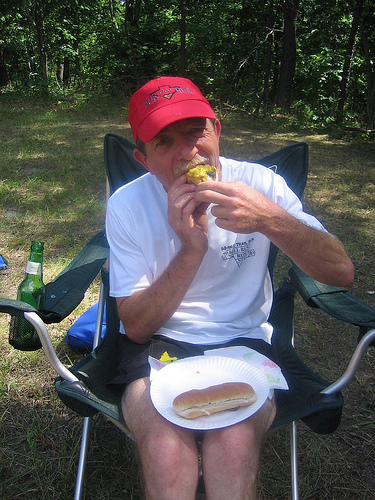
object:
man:
[103, 75, 353, 500]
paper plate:
[148, 355, 270, 432]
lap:
[137, 427, 201, 494]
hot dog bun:
[173, 381, 258, 420]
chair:
[3, 135, 375, 500]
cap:
[128, 74, 217, 147]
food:
[186, 164, 218, 188]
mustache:
[173, 157, 208, 176]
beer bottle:
[9, 240, 48, 351]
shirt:
[100, 157, 317, 344]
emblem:
[219, 234, 258, 269]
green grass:
[12, 124, 102, 209]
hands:
[165, 180, 211, 252]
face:
[135, 115, 222, 193]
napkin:
[204, 345, 289, 389]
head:
[127, 76, 222, 190]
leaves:
[222, 23, 233, 38]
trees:
[308, 0, 373, 135]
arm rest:
[290, 266, 374, 331]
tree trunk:
[276, 1, 297, 116]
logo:
[143, 84, 194, 109]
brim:
[131, 106, 218, 142]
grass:
[319, 147, 362, 177]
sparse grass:
[6, 404, 59, 466]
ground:
[8, 118, 373, 276]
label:
[23, 259, 41, 275]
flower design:
[261, 358, 278, 370]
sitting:
[86, 323, 313, 426]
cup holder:
[8, 299, 48, 352]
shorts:
[110, 335, 290, 402]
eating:
[173, 160, 220, 194]